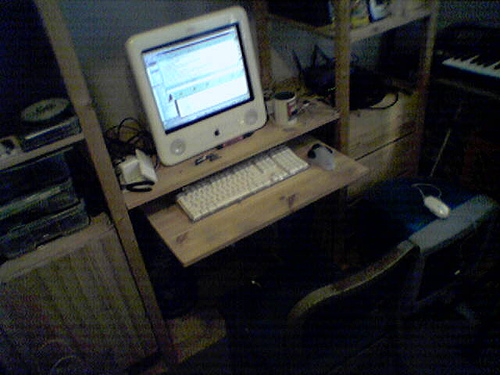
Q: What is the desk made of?
A: Wood.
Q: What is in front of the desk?
A: A chair.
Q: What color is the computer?
A: White.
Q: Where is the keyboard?
A: Under the computer.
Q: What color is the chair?
A: Black.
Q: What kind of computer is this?
A: A Mac.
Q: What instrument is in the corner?
A: A keyboard.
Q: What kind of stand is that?
A: A wooden stand.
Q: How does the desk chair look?
A: Very old.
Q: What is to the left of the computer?
A: A stack of CDs.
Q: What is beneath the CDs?
A: Some black cases.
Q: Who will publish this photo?
A: A computer magazine.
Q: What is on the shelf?
A: Keyboard.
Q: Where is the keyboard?
A: On the shelf.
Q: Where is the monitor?
A: Above the keyboard.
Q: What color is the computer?
A: White.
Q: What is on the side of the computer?
A: Shelving.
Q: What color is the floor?
A: Brown.